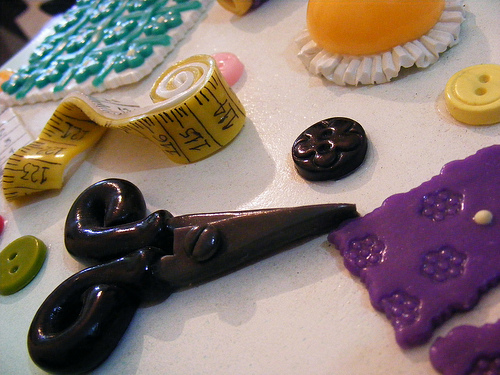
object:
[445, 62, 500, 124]
button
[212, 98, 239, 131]
black letters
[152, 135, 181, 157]
black letters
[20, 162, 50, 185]
black letters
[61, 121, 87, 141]
black letters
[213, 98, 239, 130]
number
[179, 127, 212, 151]
number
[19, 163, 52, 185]
number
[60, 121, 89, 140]
number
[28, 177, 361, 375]
scissor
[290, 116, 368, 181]
circle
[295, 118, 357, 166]
flower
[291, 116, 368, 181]
button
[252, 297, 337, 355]
view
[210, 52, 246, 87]
button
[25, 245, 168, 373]
handle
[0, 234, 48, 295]
button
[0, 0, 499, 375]
cake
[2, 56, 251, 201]
measuring tape